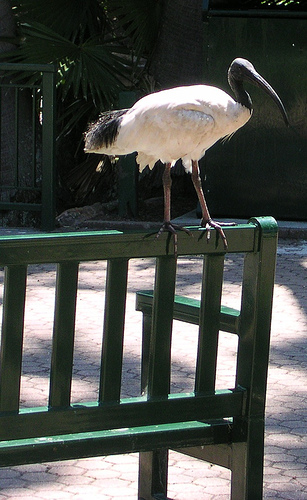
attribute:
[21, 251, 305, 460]
bench — green, wooden, slated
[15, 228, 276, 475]
bench — slated, green, wooden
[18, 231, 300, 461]
bench — green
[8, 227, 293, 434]
bench — wooden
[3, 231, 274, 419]
bench — wooden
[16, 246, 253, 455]
bench — wooden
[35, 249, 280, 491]
bench — wooden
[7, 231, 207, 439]
bench — wooden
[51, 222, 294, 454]
bench — wooden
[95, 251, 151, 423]
plank — wooden, green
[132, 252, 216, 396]
plank — green, wooden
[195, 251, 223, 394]
plank — green, wooden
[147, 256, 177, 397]
plank — wooden, green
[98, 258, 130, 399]
plank — green, wooden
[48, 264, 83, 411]
plank — wooden, green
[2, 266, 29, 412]
plank — green, wooden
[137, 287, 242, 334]
plank — wooden, green